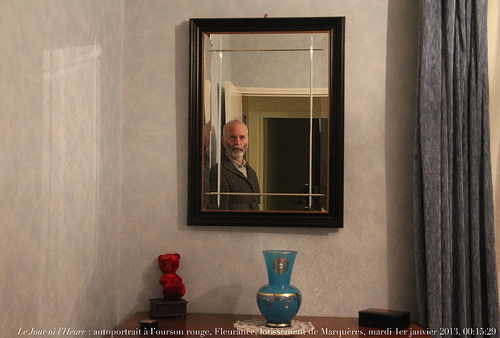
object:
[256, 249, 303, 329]
vase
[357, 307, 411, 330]
box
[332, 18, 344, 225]
black/framed mirror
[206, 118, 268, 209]
man's reflection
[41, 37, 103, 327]
light glimmer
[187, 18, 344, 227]
mirror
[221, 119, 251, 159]
man's head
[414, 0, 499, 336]
blue curtains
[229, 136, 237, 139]
man's eyes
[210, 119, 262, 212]
man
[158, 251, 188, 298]
bear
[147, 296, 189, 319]
box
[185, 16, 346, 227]
frame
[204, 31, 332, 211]
reflection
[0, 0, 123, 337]
wall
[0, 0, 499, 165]
room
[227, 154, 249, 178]
shirt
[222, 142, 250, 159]
beard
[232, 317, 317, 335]
doilie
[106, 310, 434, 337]
chest